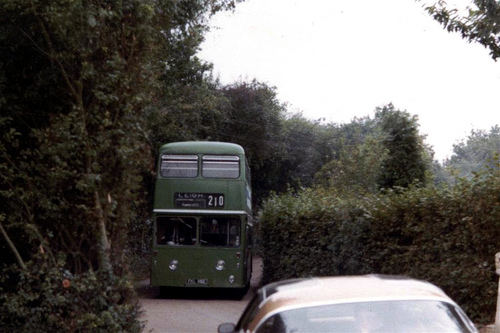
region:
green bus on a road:
[142, 135, 261, 296]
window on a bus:
[198, 152, 242, 184]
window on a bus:
[159, 150, 201, 180]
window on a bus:
[195, 210, 242, 248]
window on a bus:
[155, 213, 202, 249]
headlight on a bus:
[167, 258, 179, 272]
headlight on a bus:
[211, 258, 229, 273]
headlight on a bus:
[225, 274, 237, 284]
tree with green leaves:
[365, 102, 432, 189]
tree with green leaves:
[309, 130, 384, 205]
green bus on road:
[149, 140, 249, 294]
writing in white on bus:
[206, 192, 225, 208]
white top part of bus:
[161, 152, 198, 179]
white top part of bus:
[203, 151, 238, 178]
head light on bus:
[217, 260, 225, 270]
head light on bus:
[170, 260, 177, 270]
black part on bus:
[172, 194, 219, 206]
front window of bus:
[154, 213, 238, 245]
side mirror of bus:
[245, 225, 254, 248]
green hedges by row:
[260, 192, 497, 307]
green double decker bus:
[129, 131, 256, 290]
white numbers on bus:
[184, 188, 226, 207]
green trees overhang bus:
[4, 20, 202, 214]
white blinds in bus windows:
[164, 146, 250, 171]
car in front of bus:
[219, 236, 436, 322]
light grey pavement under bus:
[144, 303, 224, 329]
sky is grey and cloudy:
[242, 20, 495, 162]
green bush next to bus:
[277, 180, 497, 281]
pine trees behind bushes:
[375, 121, 417, 187]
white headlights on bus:
[164, 255, 234, 287]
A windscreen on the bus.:
[162, 156, 239, 181]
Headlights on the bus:
[163, 255, 233, 277]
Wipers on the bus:
[170, 226, 201, 248]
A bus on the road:
[145, 133, 255, 293]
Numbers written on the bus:
[205, 191, 227, 208]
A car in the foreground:
[246, 264, 469, 331]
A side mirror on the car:
[214, 319, 238, 331]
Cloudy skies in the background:
[335, 36, 414, 101]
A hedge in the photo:
[351, 196, 475, 261]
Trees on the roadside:
[30, 103, 127, 302]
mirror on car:
[220, 322, 232, 331]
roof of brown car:
[242, 278, 454, 331]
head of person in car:
[352, 308, 379, 325]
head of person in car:
[272, 312, 314, 329]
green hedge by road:
[265, 202, 497, 300]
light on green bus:
[215, 260, 228, 270]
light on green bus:
[166, 260, 174, 270]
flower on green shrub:
[63, 280, 69, 290]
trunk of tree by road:
[89, 188, 108, 285]